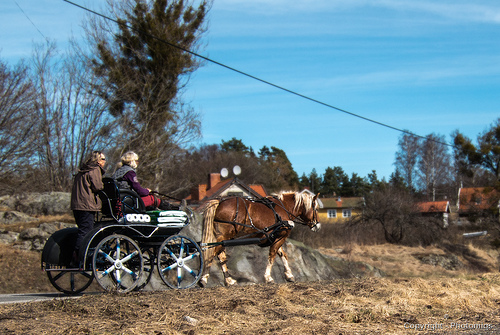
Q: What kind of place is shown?
A: It is a town.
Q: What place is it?
A: It is a town.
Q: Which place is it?
A: It is a town.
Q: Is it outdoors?
A: Yes, it is outdoors.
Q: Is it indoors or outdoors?
A: It is outdoors.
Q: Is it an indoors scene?
A: No, it is outdoors.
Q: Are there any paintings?
A: No, there are no paintings.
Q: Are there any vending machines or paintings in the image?
A: No, there are no paintings or vending machines.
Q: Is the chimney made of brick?
A: Yes, the chimney is made of brick.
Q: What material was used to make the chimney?
A: The chimney is made of brick.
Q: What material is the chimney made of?
A: The chimney is made of brick.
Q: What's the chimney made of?
A: The chimney is made of brick.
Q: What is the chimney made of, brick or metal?
A: The chimney is made of brick.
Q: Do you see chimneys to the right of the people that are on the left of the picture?
A: Yes, there is a chimney to the right of the people.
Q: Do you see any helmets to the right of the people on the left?
A: No, there is a chimney to the right of the people.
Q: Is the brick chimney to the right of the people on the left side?
A: Yes, the chimney is to the right of the people.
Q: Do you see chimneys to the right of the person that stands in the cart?
A: Yes, there is a chimney to the right of the person.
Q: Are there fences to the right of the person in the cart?
A: No, there is a chimney to the right of the person.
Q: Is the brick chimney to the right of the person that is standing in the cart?
A: Yes, the chimney is to the right of the person.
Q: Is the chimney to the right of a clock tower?
A: No, the chimney is to the right of the person.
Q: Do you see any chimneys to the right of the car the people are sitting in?
A: Yes, there is a chimney to the right of the car.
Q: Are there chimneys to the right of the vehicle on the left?
A: Yes, there is a chimney to the right of the car.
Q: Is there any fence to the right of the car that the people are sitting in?
A: No, there is a chimney to the right of the car.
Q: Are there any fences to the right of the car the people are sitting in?
A: No, there is a chimney to the right of the car.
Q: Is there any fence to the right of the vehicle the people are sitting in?
A: No, there is a chimney to the right of the car.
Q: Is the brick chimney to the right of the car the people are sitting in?
A: Yes, the chimney is to the right of the car.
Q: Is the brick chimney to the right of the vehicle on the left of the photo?
A: Yes, the chimney is to the right of the car.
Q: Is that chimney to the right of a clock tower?
A: No, the chimney is to the right of the car.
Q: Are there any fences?
A: No, there are no fences.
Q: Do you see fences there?
A: No, there are no fences.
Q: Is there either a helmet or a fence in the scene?
A: No, there are no fences or helmets.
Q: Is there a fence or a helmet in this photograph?
A: No, there are no fences or helmets.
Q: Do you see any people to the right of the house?
A: No, the person is to the left of the house.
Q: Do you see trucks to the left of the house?
A: No, there is a person to the left of the house.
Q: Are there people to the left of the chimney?
A: Yes, there is a person to the left of the chimney.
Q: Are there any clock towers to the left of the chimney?
A: No, there is a person to the left of the chimney.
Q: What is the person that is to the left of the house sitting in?
A: The person is sitting in the car.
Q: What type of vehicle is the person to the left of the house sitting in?
A: The person is sitting in the car.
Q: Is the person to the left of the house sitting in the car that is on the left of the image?
A: Yes, the person is sitting in the car.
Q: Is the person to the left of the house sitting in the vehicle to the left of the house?
A: Yes, the person is sitting in the car.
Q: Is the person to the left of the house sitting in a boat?
A: No, the person is sitting in the car.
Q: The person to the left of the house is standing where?
A: The person is standing in the cart.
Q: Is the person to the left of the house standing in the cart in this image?
A: Yes, the person is standing in the cart.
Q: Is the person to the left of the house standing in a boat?
A: No, the person is standing in the cart.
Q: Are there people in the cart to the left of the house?
A: Yes, there is a person in the cart.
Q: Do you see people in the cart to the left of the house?
A: Yes, there is a person in the cart.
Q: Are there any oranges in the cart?
A: No, there is a person in the cart.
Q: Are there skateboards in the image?
A: No, there are no skateboards.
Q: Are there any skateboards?
A: No, there are no skateboards.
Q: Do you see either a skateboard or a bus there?
A: No, there are no skateboards or buses.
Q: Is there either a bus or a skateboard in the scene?
A: No, there are no skateboards or buses.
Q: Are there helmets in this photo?
A: No, there are no helmets.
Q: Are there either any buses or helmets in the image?
A: No, there are no helmets or buses.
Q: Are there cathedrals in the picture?
A: No, there are no cathedrals.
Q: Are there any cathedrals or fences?
A: No, there are no cathedrals or fences.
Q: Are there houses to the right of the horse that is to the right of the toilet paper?
A: Yes, there is a house to the right of the horse.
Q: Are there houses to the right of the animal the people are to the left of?
A: Yes, there is a house to the right of the horse.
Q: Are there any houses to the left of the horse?
A: No, the house is to the right of the horse.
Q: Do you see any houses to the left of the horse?
A: No, the house is to the right of the horse.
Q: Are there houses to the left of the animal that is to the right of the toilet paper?
A: No, the house is to the right of the horse.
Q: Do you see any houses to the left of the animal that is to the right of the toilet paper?
A: No, the house is to the right of the horse.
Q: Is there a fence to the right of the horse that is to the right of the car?
A: No, there is a house to the right of the horse.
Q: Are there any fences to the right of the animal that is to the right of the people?
A: No, there is a house to the right of the horse.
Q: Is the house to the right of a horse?
A: Yes, the house is to the right of a horse.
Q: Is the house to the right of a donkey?
A: No, the house is to the right of a horse.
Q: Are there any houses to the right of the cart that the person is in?
A: Yes, there is a house to the right of the cart.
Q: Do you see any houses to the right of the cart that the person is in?
A: Yes, there is a house to the right of the cart.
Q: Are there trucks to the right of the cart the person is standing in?
A: No, there is a house to the right of the cart.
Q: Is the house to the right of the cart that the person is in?
A: Yes, the house is to the right of the cart.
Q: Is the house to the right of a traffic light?
A: No, the house is to the right of the cart.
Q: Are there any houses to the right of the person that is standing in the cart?
A: Yes, there is a house to the right of the person.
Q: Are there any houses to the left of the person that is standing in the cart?
A: No, the house is to the right of the person.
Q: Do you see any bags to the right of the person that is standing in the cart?
A: No, there is a house to the right of the person.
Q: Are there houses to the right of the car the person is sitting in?
A: Yes, there is a house to the right of the car.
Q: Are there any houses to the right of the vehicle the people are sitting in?
A: Yes, there is a house to the right of the car.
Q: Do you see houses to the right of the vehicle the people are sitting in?
A: Yes, there is a house to the right of the car.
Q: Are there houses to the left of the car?
A: No, the house is to the right of the car.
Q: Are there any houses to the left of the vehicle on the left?
A: No, the house is to the right of the car.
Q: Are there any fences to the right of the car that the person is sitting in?
A: No, there is a house to the right of the car.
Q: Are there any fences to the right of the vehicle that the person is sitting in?
A: No, there is a house to the right of the car.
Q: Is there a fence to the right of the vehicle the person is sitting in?
A: No, there is a house to the right of the car.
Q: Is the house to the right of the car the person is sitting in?
A: Yes, the house is to the right of the car.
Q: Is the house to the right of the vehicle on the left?
A: Yes, the house is to the right of the car.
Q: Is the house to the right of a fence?
A: No, the house is to the right of the car.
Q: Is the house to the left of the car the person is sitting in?
A: No, the house is to the right of the car.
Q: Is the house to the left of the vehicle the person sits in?
A: No, the house is to the right of the car.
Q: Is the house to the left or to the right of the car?
A: The house is to the right of the car.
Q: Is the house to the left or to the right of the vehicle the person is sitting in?
A: The house is to the right of the car.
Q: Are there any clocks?
A: No, there are no clocks.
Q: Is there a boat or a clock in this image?
A: No, there are no clocks or boats.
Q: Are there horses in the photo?
A: Yes, there is a horse.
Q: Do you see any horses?
A: Yes, there is a horse.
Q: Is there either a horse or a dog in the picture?
A: Yes, there is a horse.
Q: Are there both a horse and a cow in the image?
A: No, there is a horse but no cows.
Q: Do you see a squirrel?
A: No, there are no squirrels.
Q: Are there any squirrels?
A: No, there are no squirrels.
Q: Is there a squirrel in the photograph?
A: No, there are no squirrels.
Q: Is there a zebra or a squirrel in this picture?
A: No, there are no squirrels or zebras.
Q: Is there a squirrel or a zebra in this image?
A: No, there are no squirrels or zebras.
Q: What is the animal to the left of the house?
A: The animal is a horse.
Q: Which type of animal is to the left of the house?
A: The animal is a horse.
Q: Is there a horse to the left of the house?
A: Yes, there is a horse to the left of the house.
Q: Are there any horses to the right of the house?
A: No, the horse is to the left of the house.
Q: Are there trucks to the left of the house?
A: No, there is a horse to the left of the house.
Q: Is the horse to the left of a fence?
A: No, the horse is to the left of the house.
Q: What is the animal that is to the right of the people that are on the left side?
A: The animal is a horse.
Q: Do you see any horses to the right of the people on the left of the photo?
A: Yes, there is a horse to the right of the people.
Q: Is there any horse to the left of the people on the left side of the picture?
A: No, the horse is to the right of the people.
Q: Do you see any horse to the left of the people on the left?
A: No, the horse is to the right of the people.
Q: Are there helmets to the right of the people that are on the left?
A: No, there is a horse to the right of the people.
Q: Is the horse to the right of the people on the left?
A: Yes, the horse is to the right of the people.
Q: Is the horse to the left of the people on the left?
A: No, the horse is to the right of the people.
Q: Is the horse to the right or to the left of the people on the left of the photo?
A: The horse is to the right of the people.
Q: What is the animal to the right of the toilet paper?
A: The animal is a horse.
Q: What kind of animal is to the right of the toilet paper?
A: The animal is a horse.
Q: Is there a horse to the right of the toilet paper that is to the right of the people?
A: Yes, there is a horse to the right of the toilet paper.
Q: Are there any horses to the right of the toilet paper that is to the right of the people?
A: Yes, there is a horse to the right of the toilet paper.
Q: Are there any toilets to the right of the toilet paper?
A: No, there is a horse to the right of the toilet paper.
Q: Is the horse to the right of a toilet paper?
A: Yes, the horse is to the right of a toilet paper.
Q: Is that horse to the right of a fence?
A: No, the horse is to the right of a toilet paper.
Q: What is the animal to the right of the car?
A: The animal is a horse.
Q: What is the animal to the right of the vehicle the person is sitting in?
A: The animal is a horse.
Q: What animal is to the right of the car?
A: The animal is a horse.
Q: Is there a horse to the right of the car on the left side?
A: Yes, there is a horse to the right of the car.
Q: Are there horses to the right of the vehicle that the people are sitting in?
A: Yes, there is a horse to the right of the car.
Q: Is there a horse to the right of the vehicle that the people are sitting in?
A: Yes, there is a horse to the right of the car.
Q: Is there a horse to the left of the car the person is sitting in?
A: No, the horse is to the right of the car.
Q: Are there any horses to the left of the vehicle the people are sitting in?
A: No, the horse is to the right of the car.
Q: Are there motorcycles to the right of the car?
A: No, there is a horse to the right of the car.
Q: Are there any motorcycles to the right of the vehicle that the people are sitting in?
A: No, there is a horse to the right of the car.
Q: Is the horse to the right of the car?
A: Yes, the horse is to the right of the car.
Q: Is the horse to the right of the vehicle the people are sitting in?
A: Yes, the horse is to the right of the car.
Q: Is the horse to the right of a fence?
A: No, the horse is to the right of the car.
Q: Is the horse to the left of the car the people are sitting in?
A: No, the horse is to the right of the car.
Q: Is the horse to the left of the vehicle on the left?
A: No, the horse is to the right of the car.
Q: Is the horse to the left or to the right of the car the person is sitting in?
A: The horse is to the right of the car.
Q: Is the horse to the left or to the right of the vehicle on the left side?
A: The horse is to the right of the car.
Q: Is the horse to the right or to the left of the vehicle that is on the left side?
A: The horse is to the right of the car.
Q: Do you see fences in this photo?
A: No, there are no fences.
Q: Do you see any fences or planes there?
A: No, there are no fences or planes.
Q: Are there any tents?
A: No, there are no tents.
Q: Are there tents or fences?
A: No, there are no tents or fences.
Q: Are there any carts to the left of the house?
A: Yes, there is a cart to the left of the house.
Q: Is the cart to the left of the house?
A: Yes, the cart is to the left of the house.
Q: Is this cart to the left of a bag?
A: No, the cart is to the left of the house.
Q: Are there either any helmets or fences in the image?
A: No, there are no fences or helmets.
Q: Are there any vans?
A: No, there are no vans.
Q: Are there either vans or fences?
A: No, there are no vans or fences.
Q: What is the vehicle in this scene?
A: The vehicle is a car.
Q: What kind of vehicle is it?
A: The vehicle is a car.